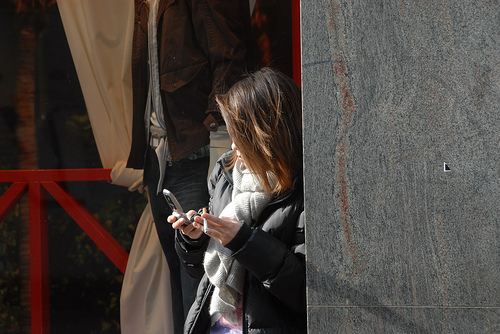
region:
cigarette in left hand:
[190, 211, 215, 231]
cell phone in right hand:
[156, 192, 201, 230]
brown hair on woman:
[204, 62, 321, 196]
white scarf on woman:
[200, 171, 283, 318]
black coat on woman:
[170, 150, 312, 331]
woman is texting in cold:
[153, 62, 321, 332]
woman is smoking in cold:
[153, 77, 333, 331]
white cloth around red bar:
[108, 189, 187, 316]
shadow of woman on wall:
[302, 263, 412, 326]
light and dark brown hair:
[208, 84, 315, 167]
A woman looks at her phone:
[130, 47, 336, 323]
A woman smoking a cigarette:
[142, 50, 318, 281]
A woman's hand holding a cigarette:
[181, 195, 252, 256]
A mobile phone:
[150, 175, 205, 245]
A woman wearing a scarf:
[151, 36, 321, 316]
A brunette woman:
[205, 55, 295, 215]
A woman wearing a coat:
[140, 45, 295, 326]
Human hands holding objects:
[145, 172, 275, 277]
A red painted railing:
[5, 125, 112, 306]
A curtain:
[47, 1, 157, 319]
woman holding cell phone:
[161, 68, 303, 331]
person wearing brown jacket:
[123, 0, 257, 332]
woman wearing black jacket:
[167, 66, 309, 333]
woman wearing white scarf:
[160, 65, 310, 332]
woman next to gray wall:
[168, 0, 496, 331]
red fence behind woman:
[0, 155, 240, 330]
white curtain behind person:
[47, 0, 233, 330]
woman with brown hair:
[161, 60, 306, 330]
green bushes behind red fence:
[0, 190, 155, 330]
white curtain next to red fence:
[0, 0, 166, 331]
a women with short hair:
[57, 20, 413, 331]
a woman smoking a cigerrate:
[149, 15, 376, 332]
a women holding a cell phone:
[82, 0, 375, 330]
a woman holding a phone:
[59, 35, 482, 331]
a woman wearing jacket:
[100, 47, 395, 311]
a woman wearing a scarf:
[117, 85, 407, 332]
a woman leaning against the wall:
[86, 21, 410, 323]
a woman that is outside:
[65, 22, 419, 307]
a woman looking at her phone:
[10, 59, 365, 328]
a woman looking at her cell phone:
[91, 52, 408, 325]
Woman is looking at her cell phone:
[158, 55, 303, 256]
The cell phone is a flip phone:
[142, 167, 210, 258]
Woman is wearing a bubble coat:
[140, 153, 312, 330]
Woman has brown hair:
[205, 63, 310, 200]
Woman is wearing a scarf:
[166, 145, 282, 303]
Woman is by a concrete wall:
[281, 1, 491, 326]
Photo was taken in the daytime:
[5, 0, 465, 330]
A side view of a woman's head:
[205, 80, 300, 180]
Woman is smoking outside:
[190, 195, 240, 255]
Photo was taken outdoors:
[5, 6, 491, 326]